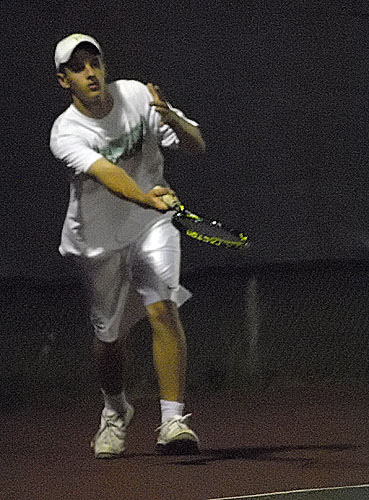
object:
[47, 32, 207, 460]
player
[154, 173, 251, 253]
racket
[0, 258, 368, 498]
court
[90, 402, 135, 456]
shoe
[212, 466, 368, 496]
line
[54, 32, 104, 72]
hat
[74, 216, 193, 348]
short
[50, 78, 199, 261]
shirt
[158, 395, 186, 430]
sock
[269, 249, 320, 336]
fence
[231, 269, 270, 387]
pole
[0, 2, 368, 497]
photo